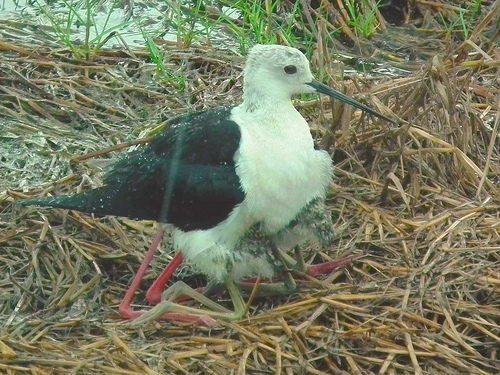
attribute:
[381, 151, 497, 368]
vegetation — brown, dry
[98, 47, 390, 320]
bird — standing, black, white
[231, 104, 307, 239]
chest — white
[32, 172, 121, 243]
tail — black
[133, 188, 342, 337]
legs — red, long, brown, pink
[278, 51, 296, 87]
eye — black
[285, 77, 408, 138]
beak — long, black, sharp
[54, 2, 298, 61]
grass — green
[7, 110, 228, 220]
wing — black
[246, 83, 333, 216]
feathers — white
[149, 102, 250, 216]
feathers — black